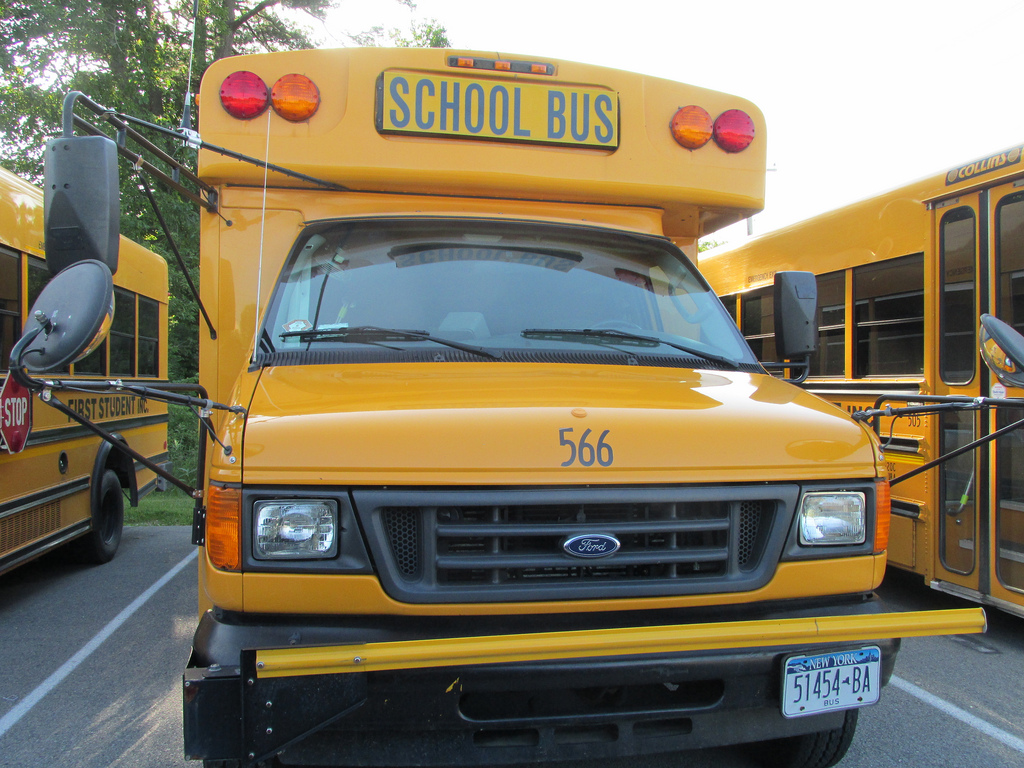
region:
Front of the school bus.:
[198, 46, 885, 755]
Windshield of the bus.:
[259, 209, 763, 374]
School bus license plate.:
[779, 643, 878, 713]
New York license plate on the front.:
[778, 642, 874, 712]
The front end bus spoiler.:
[345, 475, 797, 596]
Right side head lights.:
[198, 475, 363, 568]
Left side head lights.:
[789, 478, 887, 549]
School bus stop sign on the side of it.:
[2, 367, 29, 448]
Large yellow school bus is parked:
[21, 44, 1021, 766]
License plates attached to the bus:
[768, 647, 882, 715]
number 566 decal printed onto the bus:
[555, 416, 617, 477]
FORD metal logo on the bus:
[563, 531, 620, 567]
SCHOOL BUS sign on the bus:
[374, 66, 622, 155]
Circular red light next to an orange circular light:
[712, 102, 760, 157]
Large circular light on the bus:
[5, 259, 250, 424]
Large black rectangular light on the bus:
[45, 89, 340, 277]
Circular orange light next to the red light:
[266, 69, 320, 124]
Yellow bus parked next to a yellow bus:
[697, 138, 1021, 638]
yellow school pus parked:
[192, 48, 993, 766]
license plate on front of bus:
[779, 644, 894, 725]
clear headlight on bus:
[246, 492, 344, 566]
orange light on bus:
[186, 481, 260, 579]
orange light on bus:
[866, 478, 899, 549]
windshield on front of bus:
[251, 215, 754, 362]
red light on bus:
[701, 105, 760, 151]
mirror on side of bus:
[776, 268, 830, 387]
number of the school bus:
[548, 411, 635, 469]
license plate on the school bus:
[792, 632, 957, 737]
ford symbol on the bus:
[538, 518, 643, 573]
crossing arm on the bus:
[219, 610, 1022, 690]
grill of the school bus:
[358, 480, 830, 621]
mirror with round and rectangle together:
[17, 83, 230, 448]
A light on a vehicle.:
[242, 492, 367, 573]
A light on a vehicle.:
[802, 481, 866, 545]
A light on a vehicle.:
[231, 62, 277, 117]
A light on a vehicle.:
[272, 74, 318, 114]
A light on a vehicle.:
[670, 103, 712, 146]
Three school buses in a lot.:
[5, 63, 1017, 728]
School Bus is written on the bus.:
[354, 62, 636, 158]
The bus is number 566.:
[555, 413, 626, 481]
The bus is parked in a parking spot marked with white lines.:
[68, 512, 1011, 766]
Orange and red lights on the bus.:
[198, 57, 338, 128]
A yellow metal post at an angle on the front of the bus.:
[214, 594, 1003, 703]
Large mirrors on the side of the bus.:
[9, 76, 284, 498]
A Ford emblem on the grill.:
[549, 522, 642, 565]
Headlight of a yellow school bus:
[790, 493, 874, 551]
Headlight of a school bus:
[245, 489, 344, 567]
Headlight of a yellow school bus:
[255, 496, 347, 566]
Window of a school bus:
[291, 227, 738, 376]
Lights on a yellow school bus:
[666, 102, 758, 156]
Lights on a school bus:
[215, 66, 321, 130]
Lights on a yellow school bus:
[214, 59, 328, 137]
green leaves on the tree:
[138, 47, 203, 133]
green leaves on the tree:
[53, 61, 96, 90]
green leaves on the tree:
[162, 54, 191, 112]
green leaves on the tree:
[147, 246, 218, 316]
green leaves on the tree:
[99, 158, 194, 253]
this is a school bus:
[74, 35, 1020, 715]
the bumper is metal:
[285, 461, 776, 621]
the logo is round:
[526, 485, 673, 609]